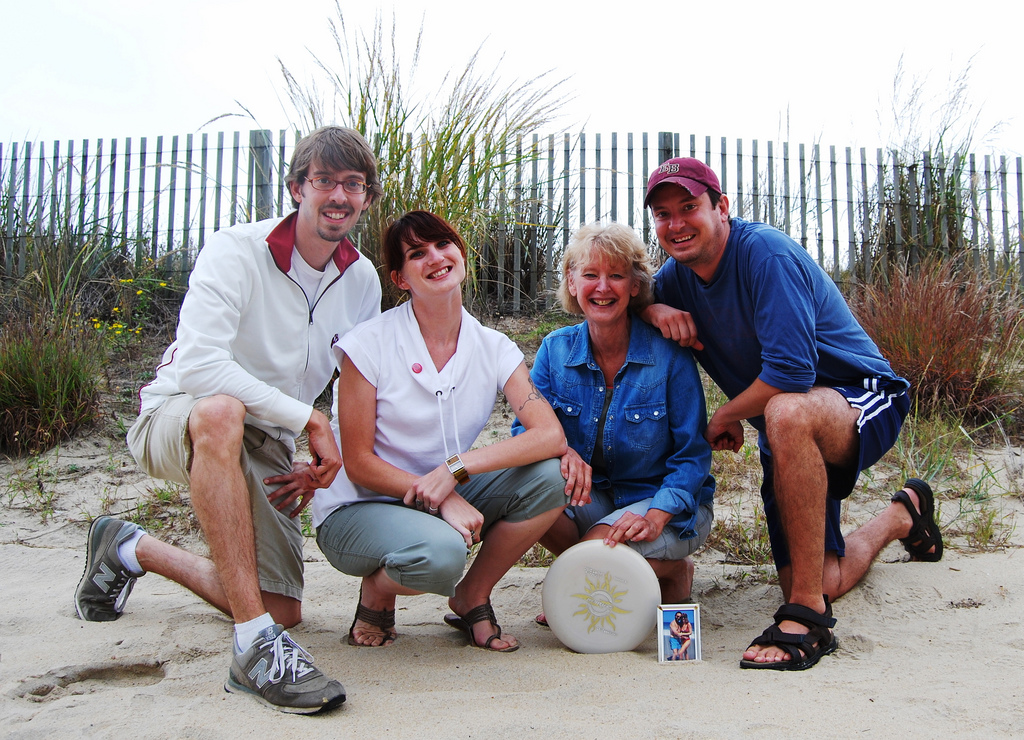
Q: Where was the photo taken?
A: It was taken at the beach.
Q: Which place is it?
A: It is a beach.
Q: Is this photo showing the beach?
A: Yes, it is showing the beach.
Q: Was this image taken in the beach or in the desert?
A: It was taken at the beach.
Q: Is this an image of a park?
A: No, the picture is showing a beach.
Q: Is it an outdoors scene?
A: Yes, it is outdoors.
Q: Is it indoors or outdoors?
A: It is outdoors.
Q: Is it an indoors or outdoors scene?
A: It is outdoors.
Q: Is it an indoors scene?
A: No, it is outdoors.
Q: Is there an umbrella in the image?
A: No, there are no umbrellas.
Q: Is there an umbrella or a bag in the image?
A: No, there are no umbrellas or bags.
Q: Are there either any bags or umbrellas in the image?
A: No, there are no umbrellas or bags.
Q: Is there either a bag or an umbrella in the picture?
A: No, there are no umbrellas or bags.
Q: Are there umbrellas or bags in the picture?
A: No, there are no umbrellas or bags.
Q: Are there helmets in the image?
A: No, there are no helmets.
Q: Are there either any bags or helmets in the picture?
A: No, there are no helmets or bags.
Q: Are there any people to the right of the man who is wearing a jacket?
A: Yes, there is a person to the right of the man.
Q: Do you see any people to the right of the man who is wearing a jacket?
A: Yes, there is a person to the right of the man.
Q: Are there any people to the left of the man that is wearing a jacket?
A: No, the person is to the right of the man.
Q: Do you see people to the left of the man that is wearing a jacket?
A: No, the person is to the right of the man.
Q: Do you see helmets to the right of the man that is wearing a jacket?
A: No, there is a person to the right of the man.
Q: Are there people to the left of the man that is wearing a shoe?
A: Yes, there is a person to the left of the man.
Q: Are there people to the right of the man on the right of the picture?
A: No, the person is to the left of the man.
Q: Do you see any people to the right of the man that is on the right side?
A: No, the person is to the left of the man.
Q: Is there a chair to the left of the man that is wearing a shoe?
A: No, there is a person to the left of the man.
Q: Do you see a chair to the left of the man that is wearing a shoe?
A: No, there is a person to the left of the man.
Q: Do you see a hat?
A: Yes, there is a hat.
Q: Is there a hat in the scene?
A: Yes, there is a hat.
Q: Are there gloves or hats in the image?
A: Yes, there is a hat.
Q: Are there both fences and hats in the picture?
A: Yes, there are both a hat and a fence.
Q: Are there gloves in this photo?
A: No, there are no gloves.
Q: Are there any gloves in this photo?
A: No, there are no gloves.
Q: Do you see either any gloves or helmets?
A: No, there are no gloves or helmets.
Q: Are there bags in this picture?
A: No, there are no bags.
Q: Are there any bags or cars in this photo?
A: No, there are no bags or cars.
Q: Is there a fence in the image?
A: Yes, there is a fence.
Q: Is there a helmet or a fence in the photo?
A: Yes, there is a fence.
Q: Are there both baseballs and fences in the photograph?
A: No, there is a fence but no baseballs.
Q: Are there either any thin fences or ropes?
A: Yes, there is a thin fence.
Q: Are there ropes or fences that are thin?
A: Yes, the fence is thin.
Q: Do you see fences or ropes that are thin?
A: Yes, the fence is thin.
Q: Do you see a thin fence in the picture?
A: Yes, there is a thin fence.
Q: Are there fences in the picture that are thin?
A: Yes, there is a fence that is thin.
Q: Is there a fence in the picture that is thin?
A: Yes, there is a fence that is thin.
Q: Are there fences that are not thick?
A: Yes, there is a thin fence.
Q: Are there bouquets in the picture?
A: No, there are no bouquets.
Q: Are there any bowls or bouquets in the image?
A: No, there are no bouquets or bowls.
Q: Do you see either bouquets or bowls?
A: No, there are no bouquets or bowls.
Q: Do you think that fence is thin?
A: Yes, the fence is thin.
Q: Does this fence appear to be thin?
A: Yes, the fence is thin.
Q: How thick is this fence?
A: The fence is thin.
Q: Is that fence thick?
A: No, the fence is thin.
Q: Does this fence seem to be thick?
A: No, the fence is thin.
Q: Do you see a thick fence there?
A: No, there is a fence but it is thin.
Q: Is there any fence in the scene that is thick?
A: No, there is a fence but it is thin.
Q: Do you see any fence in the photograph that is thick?
A: No, there is a fence but it is thin.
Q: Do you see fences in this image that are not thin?
A: No, there is a fence but it is thin.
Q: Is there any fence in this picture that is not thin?
A: No, there is a fence but it is thin.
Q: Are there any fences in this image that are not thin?
A: No, there is a fence but it is thin.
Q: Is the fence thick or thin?
A: The fence is thin.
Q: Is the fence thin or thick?
A: The fence is thin.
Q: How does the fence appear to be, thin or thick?
A: The fence is thin.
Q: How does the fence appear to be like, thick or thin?
A: The fence is thin.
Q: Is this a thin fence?
A: Yes, this is a thin fence.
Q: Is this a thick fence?
A: No, this is a thin fence.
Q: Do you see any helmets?
A: No, there are no helmets.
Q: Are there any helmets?
A: No, there are no helmets.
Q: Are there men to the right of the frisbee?
A: Yes, there is a man to the right of the frisbee.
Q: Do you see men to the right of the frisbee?
A: Yes, there is a man to the right of the frisbee.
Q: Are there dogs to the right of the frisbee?
A: No, there is a man to the right of the frisbee.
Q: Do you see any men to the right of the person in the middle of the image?
A: Yes, there is a man to the right of the person.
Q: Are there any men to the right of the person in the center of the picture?
A: Yes, there is a man to the right of the person.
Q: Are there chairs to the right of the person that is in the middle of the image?
A: No, there is a man to the right of the person.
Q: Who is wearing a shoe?
A: The man is wearing a shoe.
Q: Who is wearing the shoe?
A: The man is wearing a shoe.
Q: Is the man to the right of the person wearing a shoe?
A: Yes, the man is wearing a shoe.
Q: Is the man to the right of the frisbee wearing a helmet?
A: No, the man is wearing a shoe.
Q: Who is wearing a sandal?
A: The man is wearing a sandal.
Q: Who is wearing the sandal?
A: The man is wearing a sandal.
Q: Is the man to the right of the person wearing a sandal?
A: Yes, the man is wearing a sandal.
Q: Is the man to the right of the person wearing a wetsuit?
A: No, the man is wearing a sandal.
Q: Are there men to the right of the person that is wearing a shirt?
A: Yes, there is a man to the right of the person.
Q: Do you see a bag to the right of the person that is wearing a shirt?
A: No, there is a man to the right of the person.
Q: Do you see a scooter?
A: No, there are no scooters.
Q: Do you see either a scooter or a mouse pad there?
A: No, there are no scooters or mouse pads.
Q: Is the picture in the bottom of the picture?
A: Yes, the picture is in the bottom of the image.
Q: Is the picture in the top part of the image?
A: No, the picture is in the bottom of the image.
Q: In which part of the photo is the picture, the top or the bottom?
A: The picture is in the bottom of the image.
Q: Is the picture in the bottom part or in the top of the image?
A: The picture is in the bottom of the image.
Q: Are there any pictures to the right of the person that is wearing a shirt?
A: Yes, there is a picture to the right of the person.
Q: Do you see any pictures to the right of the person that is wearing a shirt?
A: Yes, there is a picture to the right of the person.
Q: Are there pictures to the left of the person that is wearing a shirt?
A: No, the picture is to the right of the person.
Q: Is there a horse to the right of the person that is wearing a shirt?
A: No, there is a picture to the right of the person.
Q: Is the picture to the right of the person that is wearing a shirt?
A: Yes, the picture is to the right of the person.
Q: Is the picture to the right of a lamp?
A: No, the picture is to the right of the person.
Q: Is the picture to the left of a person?
A: No, the picture is to the right of a person.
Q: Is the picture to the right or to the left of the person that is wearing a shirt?
A: The picture is to the right of the person.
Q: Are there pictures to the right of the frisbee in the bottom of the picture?
A: Yes, there is a picture to the right of the frisbee.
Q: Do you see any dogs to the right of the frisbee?
A: No, there is a picture to the right of the frisbee.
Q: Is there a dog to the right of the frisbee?
A: No, there is a picture to the right of the frisbee.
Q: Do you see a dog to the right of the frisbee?
A: No, there is a picture to the right of the frisbee.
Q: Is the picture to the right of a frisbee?
A: Yes, the picture is to the right of a frisbee.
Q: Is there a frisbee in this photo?
A: Yes, there is a frisbee.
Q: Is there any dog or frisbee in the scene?
A: Yes, there is a frisbee.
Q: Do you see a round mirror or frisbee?
A: Yes, there is a round frisbee.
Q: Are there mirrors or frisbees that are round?
A: Yes, the frisbee is round.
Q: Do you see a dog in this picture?
A: No, there are no dogs.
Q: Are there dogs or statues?
A: No, there are no dogs or statues.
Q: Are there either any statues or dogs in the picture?
A: No, there are no dogs or statues.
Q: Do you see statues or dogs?
A: No, there are no dogs or statues.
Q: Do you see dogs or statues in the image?
A: No, there are no dogs or statues.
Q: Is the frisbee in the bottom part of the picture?
A: Yes, the frisbee is in the bottom of the image.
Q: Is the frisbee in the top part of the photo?
A: No, the frisbee is in the bottom of the image.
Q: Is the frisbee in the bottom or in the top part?
A: The frisbee is in the bottom of the image.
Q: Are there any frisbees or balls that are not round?
A: No, there is a frisbee but it is round.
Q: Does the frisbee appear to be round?
A: Yes, the frisbee is round.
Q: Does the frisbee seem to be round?
A: Yes, the frisbee is round.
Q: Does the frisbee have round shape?
A: Yes, the frisbee is round.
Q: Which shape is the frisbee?
A: The frisbee is round.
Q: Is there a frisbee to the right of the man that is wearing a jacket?
A: Yes, there is a frisbee to the right of the man.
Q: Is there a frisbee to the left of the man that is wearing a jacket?
A: No, the frisbee is to the right of the man.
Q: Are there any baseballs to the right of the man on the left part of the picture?
A: No, there is a frisbee to the right of the man.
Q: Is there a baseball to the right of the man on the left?
A: No, there is a frisbee to the right of the man.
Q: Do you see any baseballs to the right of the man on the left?
A: No, there is a frisbee to the right of the man.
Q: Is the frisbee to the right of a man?
A: Yes, the frisbee is to the right of a man.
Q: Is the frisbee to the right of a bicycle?
A: No, the frisbee is to the right of a man.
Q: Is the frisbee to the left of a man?
A: No, the frisbee is to the right of a man.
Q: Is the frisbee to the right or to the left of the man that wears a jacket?
A: The frisbee is to the right of the man.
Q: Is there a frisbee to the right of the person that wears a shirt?
A: Yes, there is a frisbee to the right of the person.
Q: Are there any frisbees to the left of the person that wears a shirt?
A: No, the frisbee is to the right of the person.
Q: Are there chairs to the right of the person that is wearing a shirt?
A: No, there is a frisbee to the right of the person.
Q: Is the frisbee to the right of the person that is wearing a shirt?
A: Yes, the frisbee is to the right of the person.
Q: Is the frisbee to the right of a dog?
A: No, the frisbee is to the right of the person.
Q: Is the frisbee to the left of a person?
A: No, the frisbee is to the right of a person.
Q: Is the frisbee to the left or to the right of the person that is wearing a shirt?
A: The frisbee is to the right of the person.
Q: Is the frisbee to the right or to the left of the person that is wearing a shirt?
A: The frisbee is to the right of the person.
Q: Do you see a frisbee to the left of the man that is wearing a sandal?
A: Yes, there is a frisbee to the left of the man.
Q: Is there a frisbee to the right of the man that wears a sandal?
A: No, the frisbee is to the left of the man.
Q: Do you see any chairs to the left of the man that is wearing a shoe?
A: No, there is a frisbee to the left of the man.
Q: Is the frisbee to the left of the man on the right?
A: Yes, the frisbee is to the left of the man.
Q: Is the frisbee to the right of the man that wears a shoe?
A: No, the frisbee is to the left of the man.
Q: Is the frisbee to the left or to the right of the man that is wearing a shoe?
A: The frisbee is to the left of the man.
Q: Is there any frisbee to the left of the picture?
A: Yes, there is a frisbee to the left of the picture.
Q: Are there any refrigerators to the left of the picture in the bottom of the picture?
A: No, there is a frisbee to the left of the picture.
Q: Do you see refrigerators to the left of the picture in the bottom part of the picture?
A: No, there is a frisbee to the left of the picture.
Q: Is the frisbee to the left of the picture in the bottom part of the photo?
A: Yes, the frisbee is to the left of the picture.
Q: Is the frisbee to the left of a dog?
A: No, the frisbee is to the left of the picture.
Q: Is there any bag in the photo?
A: No, there are no bags.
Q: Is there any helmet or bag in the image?
A: No, there are no bags or helmets.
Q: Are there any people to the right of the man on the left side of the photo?
A: Yes, there is a person to the right of the man.